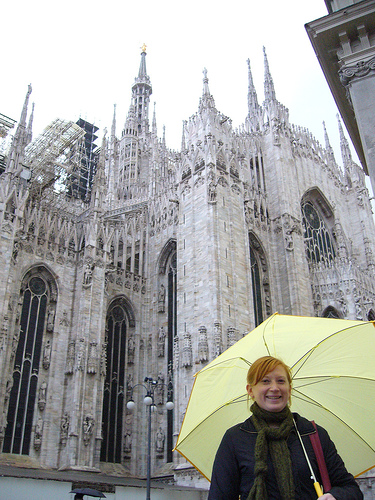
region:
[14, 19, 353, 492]
woman posing for photo in front of church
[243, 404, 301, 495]
green scarf around womans neck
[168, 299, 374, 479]
woman holding a yellow umbrella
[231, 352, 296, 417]
woman with red hair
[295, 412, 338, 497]
red strap of purse on woman's shoulder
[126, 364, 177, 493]
light with four round bulbs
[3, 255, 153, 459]
tall skiiny arched windows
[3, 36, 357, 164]
many decorative points on top of building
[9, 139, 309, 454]
large white brick building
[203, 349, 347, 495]
woman wearing a blue jacket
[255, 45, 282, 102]
spire on the tower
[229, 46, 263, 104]
spire on the tower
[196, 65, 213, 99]
spire on the tower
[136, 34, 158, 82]
spire on the tower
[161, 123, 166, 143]
spire on the tower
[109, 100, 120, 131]
spire on the tower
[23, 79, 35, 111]
spire on the tower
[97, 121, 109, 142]
spire on the tower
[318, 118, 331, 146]
spire on the tower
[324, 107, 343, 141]
spire on the tower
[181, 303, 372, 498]
woman holding yellow umbrella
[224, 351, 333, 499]
woman wearing green scarf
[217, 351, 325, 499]
woman with red hair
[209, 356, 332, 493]
woman wearing black jacket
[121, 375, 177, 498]
street lamp with white lights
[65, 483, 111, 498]
black umbrella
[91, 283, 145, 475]
window on side of cathedral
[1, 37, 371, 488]
elaborately decorated cathedral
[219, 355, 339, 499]
woman smiling outside in the rain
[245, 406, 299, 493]
green scarf on woman outside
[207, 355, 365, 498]
A lady with red hair.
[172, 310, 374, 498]
A lady with an umbrella.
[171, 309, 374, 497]
A lady holding an umbrella.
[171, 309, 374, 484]
A yellow umbrella.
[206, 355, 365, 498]
A girl with red hair.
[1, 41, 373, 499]
A church behind a lady.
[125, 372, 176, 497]
A lamp post in front of a church.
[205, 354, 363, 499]
A girl wearing a scarf.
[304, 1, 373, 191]
Part of a building.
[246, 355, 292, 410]
A girls head and face.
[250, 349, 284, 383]
woman has red hair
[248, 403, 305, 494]
woman has green scarf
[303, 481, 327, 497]
yellow handle on umbrella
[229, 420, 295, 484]
woman has blue coat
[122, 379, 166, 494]
grey pole with globe lights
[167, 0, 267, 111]
sky is bright and grey